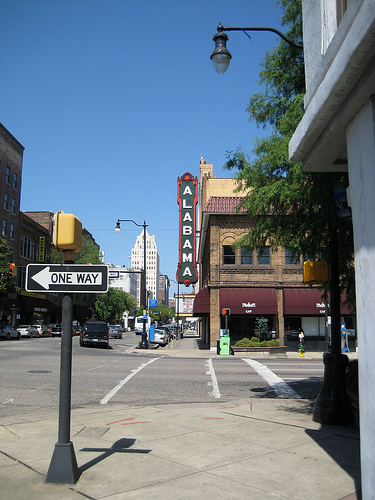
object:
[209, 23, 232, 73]
light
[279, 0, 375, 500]
wall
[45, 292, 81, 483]
pole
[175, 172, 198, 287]
board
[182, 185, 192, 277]
business name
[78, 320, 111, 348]
car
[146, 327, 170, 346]
vehicle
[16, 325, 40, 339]
vehicle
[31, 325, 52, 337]
vehicle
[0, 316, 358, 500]
road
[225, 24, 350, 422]
pole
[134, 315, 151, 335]
bus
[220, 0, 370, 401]
tree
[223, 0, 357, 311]
leave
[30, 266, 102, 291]
arrow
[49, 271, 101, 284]
text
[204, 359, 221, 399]
line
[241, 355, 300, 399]
line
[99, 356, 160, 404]
line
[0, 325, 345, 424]
asphalt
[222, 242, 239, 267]
window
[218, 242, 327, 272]
row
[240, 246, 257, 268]
window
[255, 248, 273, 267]
window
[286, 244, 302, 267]
window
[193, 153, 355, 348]
building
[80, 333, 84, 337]
light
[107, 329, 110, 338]
light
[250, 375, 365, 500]
shadow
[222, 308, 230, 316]
light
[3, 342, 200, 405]
intersection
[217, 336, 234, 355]
box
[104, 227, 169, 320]
building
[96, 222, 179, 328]
distance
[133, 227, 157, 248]
top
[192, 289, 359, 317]
awning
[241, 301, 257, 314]
text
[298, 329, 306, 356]
hydrant